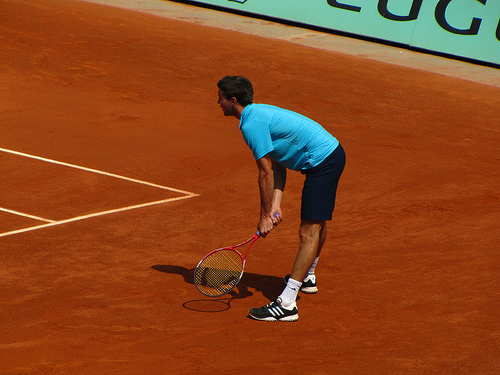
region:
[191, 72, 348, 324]
man is standing on tennis court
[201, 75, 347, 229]
man is bent from the waist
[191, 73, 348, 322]
man is playing tennis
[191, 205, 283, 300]
person holding a tennis racket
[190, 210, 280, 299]
red, silver and black tennis racket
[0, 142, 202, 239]
lines on a tennis court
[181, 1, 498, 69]
advertisement on tennis court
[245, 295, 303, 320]
black and white tennis shoe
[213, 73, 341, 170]
man wearing a blue shirt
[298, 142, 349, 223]
person wearing black shorts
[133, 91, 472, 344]
This is a tennis player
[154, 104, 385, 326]
This is a man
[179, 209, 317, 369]
This is a tennis racket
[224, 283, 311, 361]
These are tennis shoes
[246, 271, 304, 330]
The shoes are adidas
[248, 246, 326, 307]
The socks are white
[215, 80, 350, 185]
The shirt is teal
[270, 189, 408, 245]
The shorts are navy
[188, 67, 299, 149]
The hair is short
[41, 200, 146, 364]
The ground is red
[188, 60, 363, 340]
Tennis player on the court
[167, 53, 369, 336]
Man playing tennis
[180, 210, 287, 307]
racket in the man's hands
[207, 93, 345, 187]
Blue shirt on the man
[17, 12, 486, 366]
Photo taken during the day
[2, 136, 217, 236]
White lines on the court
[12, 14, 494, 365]
Tennis court is brown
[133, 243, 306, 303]
Shadow cast under the man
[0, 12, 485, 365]
Photo taken at a tennis court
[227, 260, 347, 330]
Sneakers on the man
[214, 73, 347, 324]
Man bending over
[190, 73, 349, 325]
Man holding a tennis racket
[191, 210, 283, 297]
Red and silver racket with blue handle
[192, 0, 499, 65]
Large teal sign with black lettering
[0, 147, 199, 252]
White lines on a tennis court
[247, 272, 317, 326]
Pair of black Adidas tennis shoes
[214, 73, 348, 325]
Man wearing a blue shirt and shorts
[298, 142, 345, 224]
Above the knee length navy shorts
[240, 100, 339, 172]
Light blue short sleeved shirt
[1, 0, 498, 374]
Tennis court made of dirt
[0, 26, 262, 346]
A red clay tennis court.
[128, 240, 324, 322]
Shadow of the player on the court.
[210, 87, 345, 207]
Light blue shirt on player.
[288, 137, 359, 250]
Black shorts on player.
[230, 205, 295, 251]
Blue handle on tennis racket.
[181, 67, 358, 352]
A player gripping a tennis racket with both hands.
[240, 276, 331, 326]
Black shoes with white stripes.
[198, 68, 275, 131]
Short black hair on player.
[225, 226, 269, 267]
Red color of area above racket handle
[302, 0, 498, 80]
Black lettering on side of tennis court.